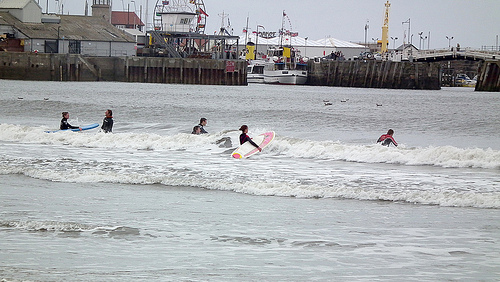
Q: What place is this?
A: It is an ocean.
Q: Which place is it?
A: It is an ocean.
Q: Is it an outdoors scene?
A: Yes, it is outdoors.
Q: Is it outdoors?
A: Yes, it is outdoors.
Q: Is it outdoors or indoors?
A: It is outdoors.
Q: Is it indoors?
A: No, it is outdoors.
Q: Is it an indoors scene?
A: No, it is outdoors.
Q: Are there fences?
A: No, there are no fences.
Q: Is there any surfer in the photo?
A: Yes, there is a surfer.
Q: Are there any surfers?
A: Yes, there is a surfer.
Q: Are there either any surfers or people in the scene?
A: Yes, there is a surfer.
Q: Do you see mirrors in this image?
A: No, there are no mirrors.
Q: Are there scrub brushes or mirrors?
A: No, there are no mirrors or scrub brushes.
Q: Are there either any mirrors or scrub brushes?
A: No, there are no mirrors or scrub brushes.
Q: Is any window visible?
A: Yes, there is a window.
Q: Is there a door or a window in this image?
A: Yes, there is a window.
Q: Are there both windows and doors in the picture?
A: No, there is a window but no doors.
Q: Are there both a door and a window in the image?
A: No, there is a window but no doors.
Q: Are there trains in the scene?
A: No, there are no trains.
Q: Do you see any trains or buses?
A: No, there are no trains or buses.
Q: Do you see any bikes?
A: No, there are no bikes.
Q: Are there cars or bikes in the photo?
A: No, there are no bikes or cars.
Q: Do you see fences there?
A: No, there are no fences.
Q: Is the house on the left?
A: Yes, the house is on the left of the image.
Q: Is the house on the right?
A: No, the house is on the left of the image.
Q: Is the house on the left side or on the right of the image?
A: The house is on the left of the image.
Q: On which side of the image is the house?
A: The house is on the left of the image.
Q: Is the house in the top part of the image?
A: Yes, the house is in the top of the image.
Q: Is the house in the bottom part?
A: No, the house is in the top of the image.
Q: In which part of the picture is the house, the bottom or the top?
A: The house is in the top of the image.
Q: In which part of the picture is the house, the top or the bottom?
A: The house is in the top of the image.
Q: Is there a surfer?
A: Yes, there is a surfer.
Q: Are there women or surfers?
A: Yes, there is a surfer.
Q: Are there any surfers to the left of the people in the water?
A: Yes, there is a surfer to the left of the people.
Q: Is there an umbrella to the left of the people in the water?
A: No, there is a surfer to the left of the people.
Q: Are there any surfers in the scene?
A: Yes, there is a surfer.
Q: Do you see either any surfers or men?
A: Yes, there is a surfer.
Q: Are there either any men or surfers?
A: Yes, there is a surfer.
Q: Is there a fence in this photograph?
A: No, there are no fences.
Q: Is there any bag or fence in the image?
A: No, there are no fences or bags.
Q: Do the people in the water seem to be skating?
A: Yes, the people are skating.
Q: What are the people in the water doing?
A: The people are skating.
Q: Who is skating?
A: The people are skating.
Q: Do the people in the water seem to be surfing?
A: No, the people are skating.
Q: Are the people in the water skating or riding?
A: The people are skating.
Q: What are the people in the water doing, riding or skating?
A: The people are skating.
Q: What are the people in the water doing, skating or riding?
A: The people are skating.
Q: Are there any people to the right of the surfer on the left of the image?
A: Yes, there are people to the right of the surfer.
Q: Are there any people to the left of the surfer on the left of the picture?
A: No, the people are to the right of the surfer.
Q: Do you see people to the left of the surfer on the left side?
A: No, the people are to the right of the surfer.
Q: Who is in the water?
A: The people are in the water.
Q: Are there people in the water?
A: Yes, there are people in the water.